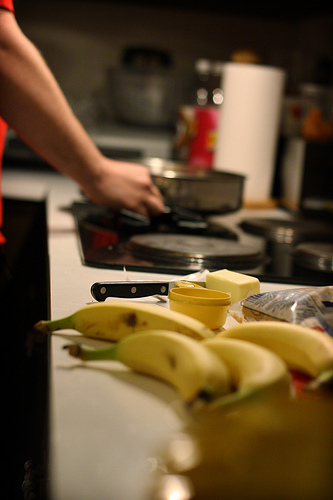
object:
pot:
[137, 155, 245, 217]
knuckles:
[141, 175, 154, 194]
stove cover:
[129, 229, 266, 266]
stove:
[72, 196, 332, 290]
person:
[0, 0, 168, 252]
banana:
[33, 297, 216, 342]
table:
[0, 167, 193, 499]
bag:
[237, 284, 332, 336]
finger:
[139, 190, 166, 215]